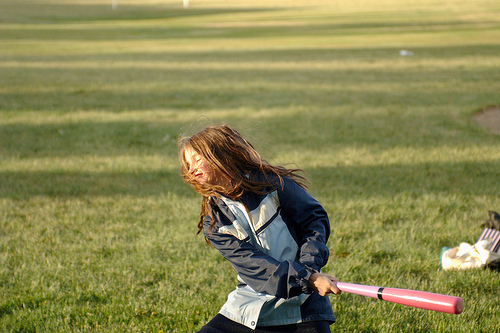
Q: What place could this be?
A: It is a park.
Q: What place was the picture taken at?
A: It was taken at the park.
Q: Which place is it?
A: It is a park.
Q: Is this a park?
A: Yes, it is a park.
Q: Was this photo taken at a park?
A: Yes, it was taken in a park.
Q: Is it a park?
A: Yes, it is a park.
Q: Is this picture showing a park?
A: Yes, it is showing a park.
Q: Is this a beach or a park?
A: It is a park.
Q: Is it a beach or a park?
A: It is a park.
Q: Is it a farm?
A: No, it is a park.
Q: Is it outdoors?
A: Yes, it is outdoors.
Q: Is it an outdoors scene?
A: Yes, it is outdoors.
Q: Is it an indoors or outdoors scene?
A: It is outdoors.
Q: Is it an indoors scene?
A: No, it is outdoors.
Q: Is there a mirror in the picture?
A: No, there are no mirrors.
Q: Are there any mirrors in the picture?
A: No, there are no mirrors.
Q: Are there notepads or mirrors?
A: No, there are no mirrors or notepads.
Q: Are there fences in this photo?
A: No, there are no fences.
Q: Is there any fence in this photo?
A: No, there are no fences.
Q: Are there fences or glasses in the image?
A: No, there are no fences or glasses.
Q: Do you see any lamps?
A: No, there are no lamps.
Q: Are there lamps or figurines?
A: No, there are no lamps or figurines.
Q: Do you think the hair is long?
A: Yes, the hair is long.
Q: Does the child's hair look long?
A: Yes, the hair is long.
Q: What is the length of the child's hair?
A: The hair is long.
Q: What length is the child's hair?
A: The hair is long.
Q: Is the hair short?
A: No, the hair is long.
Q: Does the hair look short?
A: No, the hair is long.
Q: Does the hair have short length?
A: No, the hair is long.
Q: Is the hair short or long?
A: The hair is long.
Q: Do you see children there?
A: Yes, there is a child.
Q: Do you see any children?
A: Yes, there is a child.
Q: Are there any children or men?
A: Yes, there is a child.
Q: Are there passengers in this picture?
A: No, there are no passengers.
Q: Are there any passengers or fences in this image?
A: No, there are no passengers or fences.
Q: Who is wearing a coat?
A: The child is wearing a coat.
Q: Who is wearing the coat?
A: The child is wearing a coat.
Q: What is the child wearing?
A: The child is wearing a coat.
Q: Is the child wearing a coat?
A: Yes, the child is wearing a coat.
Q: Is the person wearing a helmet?
A: No, the child is wearing a coat.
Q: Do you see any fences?
A: No, there are no fences.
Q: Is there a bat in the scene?
A: Yes, there is a bat.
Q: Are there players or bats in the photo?
A: Yes, there is a bat.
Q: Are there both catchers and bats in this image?
A: No, there is a bat but no catchers.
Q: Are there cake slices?
A: No, there are no cake slices.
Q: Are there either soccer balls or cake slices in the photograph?
A: No, there are no cake slices or soccer balls.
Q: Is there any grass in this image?
A: Yes, there is grass.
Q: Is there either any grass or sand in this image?
A: Yes, there is grass.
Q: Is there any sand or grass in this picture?
A: Yes, there is grass.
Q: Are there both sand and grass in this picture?
A: No, there is grass but no sand.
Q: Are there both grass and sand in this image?
A: No, there is grass but no sand.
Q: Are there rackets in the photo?
A: No, there are no rackets.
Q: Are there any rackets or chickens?
A: No, there are no rackets or chickens.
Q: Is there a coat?
A: Yes, there is a coat.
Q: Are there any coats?
A: Yes, there is a coat.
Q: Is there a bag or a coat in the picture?
A: Yes, there is a coat.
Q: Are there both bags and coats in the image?
A: Yes, there are both a coat and a bag.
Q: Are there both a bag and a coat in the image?
A: Yes, there are both a coat and a bag.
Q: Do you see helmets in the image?
A: No, there are no helmets.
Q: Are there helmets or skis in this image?
A: No, there are no helmets or skis.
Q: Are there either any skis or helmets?
A: No, there are no helmets or skis.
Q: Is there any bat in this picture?
A: Yes, there is a bat.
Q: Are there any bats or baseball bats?
A: Yes, there is a bat.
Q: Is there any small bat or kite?
A: Yes, there is a small bat.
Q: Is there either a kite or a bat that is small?
A: Yes, the bat is small.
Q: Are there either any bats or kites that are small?
A: Yes, the bat is small.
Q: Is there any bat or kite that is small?
A: Yes, the bat is small.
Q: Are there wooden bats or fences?
A: Yes, there is a wood bat.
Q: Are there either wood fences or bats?
A: Yes, there is a wood bat.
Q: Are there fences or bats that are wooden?
A: Yes, the bat is wooden.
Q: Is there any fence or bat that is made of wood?
A: Yes, the bat is made of wood.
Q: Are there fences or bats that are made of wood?
A: Yes, the bat is made of wood.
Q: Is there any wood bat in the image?
A: Yes, there is a wood bat.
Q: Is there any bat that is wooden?
A: Yes, there is a bat that is wooden.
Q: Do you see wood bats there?
A: Yes, there is a bat that is made of wood.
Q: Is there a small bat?
A: Yes, there is a small bat.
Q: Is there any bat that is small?
A: Yes, there is a bat that is small.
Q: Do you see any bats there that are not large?
A: Yes, there is a small bat.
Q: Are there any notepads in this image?
A: No, there are no notepads.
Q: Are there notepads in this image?
A: No, there are no notepads.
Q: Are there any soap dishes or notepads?
A: No, there are no notepads or soap dishes.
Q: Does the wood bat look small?
A: Yes, the bat is small.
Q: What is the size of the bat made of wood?
A: The bat is small.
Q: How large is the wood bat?
A: The bat is small.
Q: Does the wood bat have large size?
A: No, the bat is small.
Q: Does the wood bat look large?
A: No, the bat is small.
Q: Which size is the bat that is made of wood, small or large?
A: The bat is small.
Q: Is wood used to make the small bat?
A: Yes, the bat is made of wood.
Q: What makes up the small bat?
A: The bat is made of wood.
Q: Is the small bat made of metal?
A: No, the bat is made of wood.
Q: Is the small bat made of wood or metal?
A: The bat is made of wood.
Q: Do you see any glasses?
A: No, there are no glasses.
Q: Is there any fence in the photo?
A: No, there are no fences.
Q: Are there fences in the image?
A: No, there are no fences.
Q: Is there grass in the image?
A: Yes, there is grass.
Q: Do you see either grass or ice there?
A: Yes, there is grass.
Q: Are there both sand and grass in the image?
A: No, there is grass but no sand.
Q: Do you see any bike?
A: No, there are no bikes.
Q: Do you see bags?
A: Yes, there is a bag.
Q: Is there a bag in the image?
A: Yes, there is a bag.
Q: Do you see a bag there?
A: Yes, there is a bag.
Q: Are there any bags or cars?
A: Yes, there is a bag.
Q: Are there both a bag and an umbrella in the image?
A: No, there is a bag but no umbrellas.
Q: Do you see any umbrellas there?
A: No, there are no umbrellas.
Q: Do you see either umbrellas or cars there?
A: No, there are no umbrellas or cars.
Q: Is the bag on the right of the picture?
A: Yes, the bag is on the right of the image.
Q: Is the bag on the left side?
A: No, the bag is on the right of the image.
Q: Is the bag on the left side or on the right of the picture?
A: The bag is on the right of the image.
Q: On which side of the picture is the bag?
A: The bag is on the right of the image.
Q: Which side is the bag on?
A: The bag is on the right of the image.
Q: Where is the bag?
A: The bag is on the ground.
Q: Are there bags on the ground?
A: Yes, there is a bag on the ground.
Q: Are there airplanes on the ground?
A: No, there is a bag on the ground.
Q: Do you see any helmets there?
A: No, there are no helmets.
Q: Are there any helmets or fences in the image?
A: No, there are no helmets or fences.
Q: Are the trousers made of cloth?
A: Yes, the trousers are made of cloth.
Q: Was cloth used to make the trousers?
A: Yes, the trousers are made of cloth.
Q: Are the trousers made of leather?
A: No, the trousers are made of cloth.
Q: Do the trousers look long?
A: Yes, the trousers are long.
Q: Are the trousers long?
A: Yes, the trousers are long.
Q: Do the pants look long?
A: Yes, the pants are long.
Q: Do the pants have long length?
A: Yes, the pants are long.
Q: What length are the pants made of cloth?
A: The pants are long.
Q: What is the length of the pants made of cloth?
A: The pants are long.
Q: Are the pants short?
A: No, the pants are long.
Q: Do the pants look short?
A: No, the pants are long.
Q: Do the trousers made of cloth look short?
A: No, the pants are long.